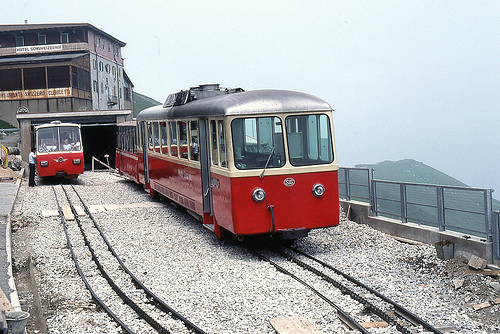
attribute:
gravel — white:
[115, 244, 309, 324]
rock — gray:
[22, 167, 499, 330]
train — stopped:
[123, 83, 388, 251]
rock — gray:
[195, 242, 202, 247]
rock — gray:
[356, 240, 385, 270]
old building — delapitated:
[0, 17, 125, 127]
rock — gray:
[53, 311, 65, 321]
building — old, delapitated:
[12, 20, 134, 115]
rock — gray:
[117, 227, 149, 248]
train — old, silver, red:
[108, 87, 349, 261]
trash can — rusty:
[434, 236, 454, 259]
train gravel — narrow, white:
[63, 220, 143, 323]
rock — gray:
[102, 208, 221, 307]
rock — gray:
[130, 213, 179, 263]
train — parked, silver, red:
[112, 82, 344, 254]